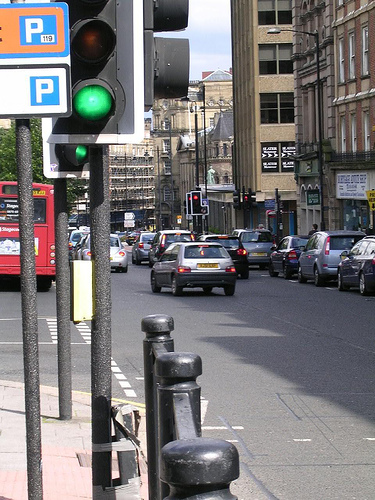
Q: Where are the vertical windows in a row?
A: Tall building.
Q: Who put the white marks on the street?
A: City worker.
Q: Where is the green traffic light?
A: Street corner.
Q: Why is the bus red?
A: Standard bus color.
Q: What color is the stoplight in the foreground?
A: Green.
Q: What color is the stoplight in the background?
A: Red.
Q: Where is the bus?
A: Across the street.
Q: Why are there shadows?
A: It is sunny.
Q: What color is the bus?
A: Red.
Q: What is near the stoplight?
A: Black posts.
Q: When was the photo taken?
A: Daytime.